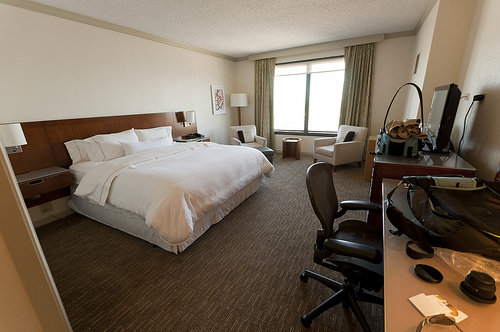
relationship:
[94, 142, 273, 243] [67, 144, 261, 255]
comforter on bed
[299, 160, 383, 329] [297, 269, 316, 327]
chair has wheels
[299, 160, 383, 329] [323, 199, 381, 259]
chair has arm rests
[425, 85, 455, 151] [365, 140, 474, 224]
tv on dresser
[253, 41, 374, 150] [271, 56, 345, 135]
drapes are on window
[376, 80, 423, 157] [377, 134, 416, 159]
bag has pockets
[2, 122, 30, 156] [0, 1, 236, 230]
lamp on wall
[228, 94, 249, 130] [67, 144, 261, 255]
lamp near bed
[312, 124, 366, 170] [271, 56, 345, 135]
chair by window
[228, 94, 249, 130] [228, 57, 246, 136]
lamp in corner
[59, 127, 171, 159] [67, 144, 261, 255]
pillows are on bed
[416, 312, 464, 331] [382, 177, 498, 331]
glasses are on desk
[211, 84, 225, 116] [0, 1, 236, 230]
picture on wall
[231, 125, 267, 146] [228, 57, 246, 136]
chair in corner